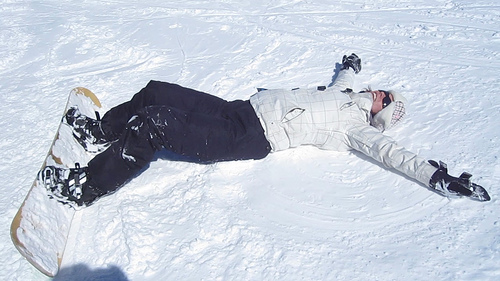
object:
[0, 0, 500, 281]
snow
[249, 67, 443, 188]
coat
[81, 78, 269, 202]
pants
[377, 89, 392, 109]
sunglasses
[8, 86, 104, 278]
snowboard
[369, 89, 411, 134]
hat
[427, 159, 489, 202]
glove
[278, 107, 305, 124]
pocket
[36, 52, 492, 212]
lady